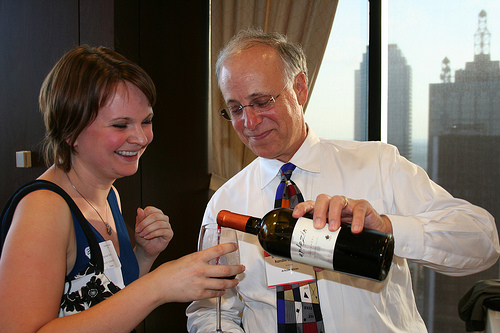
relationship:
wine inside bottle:
[252, 228, 394, 281] [217, 207, 394, 281]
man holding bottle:
[185, 27, 499, 332] [217, 207, 394, 281]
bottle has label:
[217, 207, 394, 281] [289, 216, 342, 271]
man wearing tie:
[185, 27, 499, 332] [273, 162, 326, 333]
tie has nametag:
[273, 162, 326, 333] [265, 251, 319, 288]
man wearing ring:
[185, 27, 499, 332] [342, 195, 349, 210]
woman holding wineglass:
[0, 44, 246, 332] [199, 224, 246, 333]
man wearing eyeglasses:
[185, 27, 499, 332] [219, 73, 301, 121]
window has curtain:
[208, 1, 499, 333] [209, 1, 340, 198]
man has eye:
[185, 27, 499, 332] [256, 98, 271, 107]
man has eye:
[185, 27, 499, 332] [230, 105, 242, 114]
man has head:
[185, 27, 499, 332] [217, 30, 310, 159]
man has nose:
[185, 27, 499, 332] [244, 100, 264, 130]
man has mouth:
[185, 27, 499, 332] [248, 129, 275, 140]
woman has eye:
[0, 44, 246, 332] [113, 121, 129, 129]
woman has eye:
[0, 44, 246, 332] [140, 118, 153, 125]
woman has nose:
[0, 44, 246, 332] [126, 123, 148, 146]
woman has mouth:
[0, 44, 246, 332] [114, 146, 142, 162]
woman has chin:
[0, 44, 246, 332] [114, 164, 140, 176]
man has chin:
[185, 27, 499, 332] [252, 144, 285, 159]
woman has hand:
[0, 44, 246, 332] [165, 241, 246, 304]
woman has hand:
[0, 44, 246, 332] [136, 206, 174, 256]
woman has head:
[0, 44, 246, 332] [40, 44, 155, 180]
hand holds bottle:
[292, 194, 388, 233] [217, 207, 394, 281]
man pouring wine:
[185, 27, 499, 332] [252, 228, 394, 281]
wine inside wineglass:
[217, 225, 222, 264] [199, 224, 246, 333]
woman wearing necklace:
[0, 44, 246, 332] [58, 159, 113, 235]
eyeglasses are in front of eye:
[219, 73, 301, 121] [256, 98, 271, 107]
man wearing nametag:
[185, 27, 499, 332] [265, 251, 319, 288]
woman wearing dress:
[0, 44, 246, 332] [0, 178, 141, 332]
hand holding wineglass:
[165, 241, 246, 304] [199, 224, 246, 333]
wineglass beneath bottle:
[199, 224, 246, 333] [217, 207, 394, 281]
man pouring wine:
[185, 27, 499, 332] [217, 225, 222, 264]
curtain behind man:
[209, 1, 340, 198] [185, 27, 499, 332]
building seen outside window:
[355, 44, 412, 164] [211, 4, 484, 268]